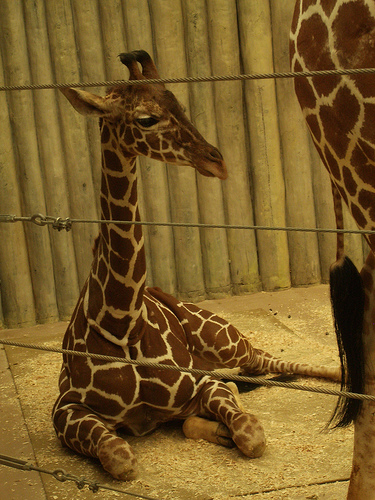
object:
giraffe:
[51, 49, 348, 479]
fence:
[0, 0, 375, 329]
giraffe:
[288, 0, 375, 500]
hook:
[31, 213, 72, 232]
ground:
[0, 284, 356, 500]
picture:
[0, 0, 375, 499]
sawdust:
[0, 290, 355, 500]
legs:
[199, 379, 266, 458]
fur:
[322, 255, 367, 431]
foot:
[216, 422, 235, 448]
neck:
[83, 117, 149, 332]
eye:
[133, 115, 159, 130]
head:
[58, 49, 229, 181]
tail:
[323, 175, 365, 429]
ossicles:
[120, 50, 147, 80]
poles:
[0, 66, 375, 90]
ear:
[58, 83, 107, 117]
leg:
[182, 416, 236, 449]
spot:
[107, 173, 130, 200]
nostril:
[204, 148, 223, 164]